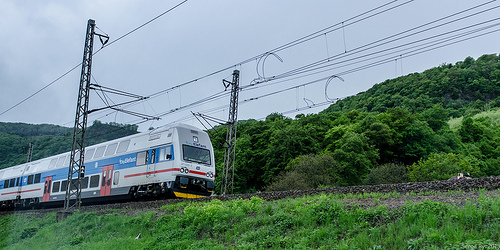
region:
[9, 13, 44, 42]
white clouds in blue sky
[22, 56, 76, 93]
white clouds in blue sky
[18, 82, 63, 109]
white clouds in blue sky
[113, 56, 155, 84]
white clouds in blue sky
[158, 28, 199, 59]
white clouds in blue sky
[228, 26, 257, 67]
white clouds in blue sky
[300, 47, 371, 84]
white clouds in blue sky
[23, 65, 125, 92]
white clouds in blue sky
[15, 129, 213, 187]
gray and red train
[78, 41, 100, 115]
gray post by tracks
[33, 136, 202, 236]
blue and white passenger train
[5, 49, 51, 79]
white clouds in blue sky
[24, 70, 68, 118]
white clouds in blue sky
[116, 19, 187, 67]
white clouds in blue sky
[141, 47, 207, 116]
white clouds in blue sky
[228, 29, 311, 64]
white clouds in blue sky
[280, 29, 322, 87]
white clouds in blue sky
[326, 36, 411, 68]
white clouds in blue sky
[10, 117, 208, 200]
red white and blue light rail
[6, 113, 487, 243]
train moving on top of slope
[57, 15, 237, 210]
towers of metal zigzag supports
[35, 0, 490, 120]
elevated straight and curved wires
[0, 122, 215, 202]
gray train with double red doors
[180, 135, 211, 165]
rectangular window on front of train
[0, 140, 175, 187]
blue stripe along side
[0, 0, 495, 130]
light blue sky with faint clouds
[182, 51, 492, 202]
green hill in front of train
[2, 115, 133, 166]
tree-covered slope in back of train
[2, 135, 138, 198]
rows of windows on different levels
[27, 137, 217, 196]
red white and blue train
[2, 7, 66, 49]
white clouds in blue sky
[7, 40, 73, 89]
white clouds in blue sky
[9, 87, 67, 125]
white clouds in blue sky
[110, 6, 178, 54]
white clouds in blue sky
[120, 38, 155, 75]
white clouds in blue sky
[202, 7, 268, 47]
white clouds in blue sky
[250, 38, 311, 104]
white clouds in blue sky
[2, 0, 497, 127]
cloud cover in sky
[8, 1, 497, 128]
wires suspended in the air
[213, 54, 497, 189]
green vegetation on hill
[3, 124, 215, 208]
passenger train on track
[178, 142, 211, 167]
front windshield of train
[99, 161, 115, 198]
double red doors of train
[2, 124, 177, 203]
train with two floors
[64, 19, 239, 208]
two metal towers for wires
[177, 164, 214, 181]
four headlights of train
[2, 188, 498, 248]
green grass on hill